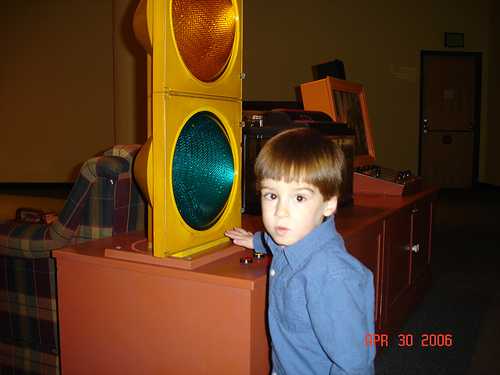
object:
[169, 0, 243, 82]
stoplight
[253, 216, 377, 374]
shirt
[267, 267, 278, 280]
button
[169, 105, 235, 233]
light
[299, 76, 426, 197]
computer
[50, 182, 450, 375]
table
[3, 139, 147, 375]
chair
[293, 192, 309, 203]
eye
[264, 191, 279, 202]
eye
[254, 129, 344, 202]
hair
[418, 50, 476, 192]
door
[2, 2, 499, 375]
room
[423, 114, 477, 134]
bar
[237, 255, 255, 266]
button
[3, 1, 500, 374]
background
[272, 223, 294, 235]
mouth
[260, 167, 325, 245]
face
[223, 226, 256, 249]
hand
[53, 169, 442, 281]
surface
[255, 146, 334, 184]
bangs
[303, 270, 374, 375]
sleeve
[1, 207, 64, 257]
arm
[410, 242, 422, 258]
opener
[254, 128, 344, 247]
head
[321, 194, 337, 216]
ear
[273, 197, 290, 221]
nose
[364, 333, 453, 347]
date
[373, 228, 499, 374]
floor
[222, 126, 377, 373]
boy